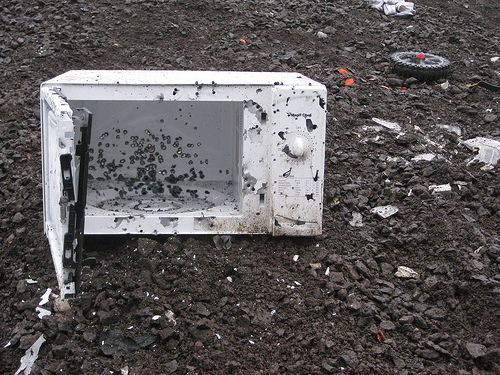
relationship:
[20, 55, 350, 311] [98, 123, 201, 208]
microwave full of bullet holes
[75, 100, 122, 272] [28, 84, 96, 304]
part breaking off door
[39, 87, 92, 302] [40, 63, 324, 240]
door on microwave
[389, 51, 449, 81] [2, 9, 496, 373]
object/ground on ground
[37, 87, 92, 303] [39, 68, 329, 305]
door of microwave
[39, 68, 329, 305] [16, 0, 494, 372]
microwave at dump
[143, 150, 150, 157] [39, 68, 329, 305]
particle in microwave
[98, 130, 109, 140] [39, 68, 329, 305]
particle in microwave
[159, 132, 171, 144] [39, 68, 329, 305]
particle in microwave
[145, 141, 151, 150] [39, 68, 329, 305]
particle in microwave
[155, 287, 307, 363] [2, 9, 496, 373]
rocks on ground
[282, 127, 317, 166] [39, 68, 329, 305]
knob on microwave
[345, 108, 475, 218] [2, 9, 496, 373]
particles on ground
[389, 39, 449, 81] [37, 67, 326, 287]
object/ground on object/ground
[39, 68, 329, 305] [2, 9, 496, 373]
microwave sitting on ground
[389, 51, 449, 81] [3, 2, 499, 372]
object/ground sitting on dirt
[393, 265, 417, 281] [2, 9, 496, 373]
rock on ground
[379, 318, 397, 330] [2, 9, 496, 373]
rock on ground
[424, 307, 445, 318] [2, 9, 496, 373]
rock on ground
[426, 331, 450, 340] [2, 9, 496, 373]
rock on ground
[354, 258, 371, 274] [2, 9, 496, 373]
rock on ground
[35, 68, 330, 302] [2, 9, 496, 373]
plastic on ground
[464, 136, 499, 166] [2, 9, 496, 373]
plastic on ground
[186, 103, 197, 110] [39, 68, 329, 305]
marks inside microwave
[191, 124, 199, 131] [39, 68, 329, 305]
marks inside microwave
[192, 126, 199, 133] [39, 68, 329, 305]
marks inside microwave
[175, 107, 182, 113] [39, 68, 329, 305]
marks inside microwave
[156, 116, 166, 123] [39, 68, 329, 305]
marks inside microwave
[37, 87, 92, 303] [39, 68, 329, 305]
door on microwave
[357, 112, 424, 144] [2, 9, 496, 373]
rock on ground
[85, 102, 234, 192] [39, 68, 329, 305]
holes in microwave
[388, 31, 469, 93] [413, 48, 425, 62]
tire has red center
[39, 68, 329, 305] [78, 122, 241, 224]
microwave has dial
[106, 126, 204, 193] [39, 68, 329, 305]
holes in microwave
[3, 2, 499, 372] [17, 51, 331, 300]
dirt in front of microwave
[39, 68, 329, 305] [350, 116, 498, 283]
microwave has pieces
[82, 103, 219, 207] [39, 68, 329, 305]
holes in back of microwave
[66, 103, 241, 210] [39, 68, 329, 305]
inside of microwave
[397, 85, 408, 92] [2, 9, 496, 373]
something sitting on ground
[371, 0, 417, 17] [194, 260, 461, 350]
cloth on ground